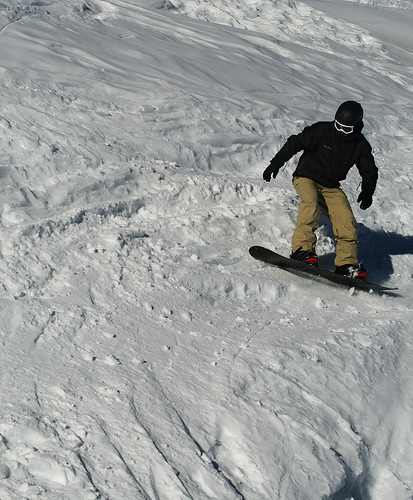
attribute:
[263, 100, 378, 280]
man — snowboarding, skiing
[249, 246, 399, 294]
snowboard — black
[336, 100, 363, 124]
hat — black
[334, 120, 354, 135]
goggles — white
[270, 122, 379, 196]
coat — black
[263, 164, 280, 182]
glove — black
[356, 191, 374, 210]
glove — black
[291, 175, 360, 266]
pants — tan, khaki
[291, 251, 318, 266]
shoe — black, orange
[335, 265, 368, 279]
shoe — black, orange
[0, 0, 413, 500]
hill — snow white covered, snow covered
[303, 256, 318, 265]
bottom — red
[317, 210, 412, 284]
shadow — on right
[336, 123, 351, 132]
lenses — black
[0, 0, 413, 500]
snow — beautiful, white, cold, deep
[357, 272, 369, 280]
bottom — red